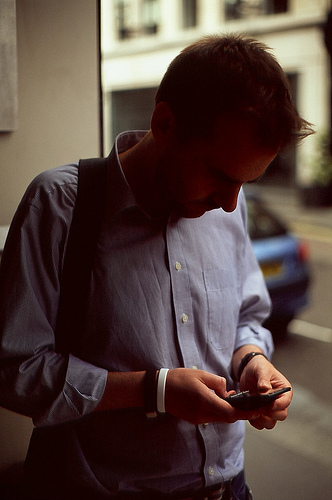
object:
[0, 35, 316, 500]
man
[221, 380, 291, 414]
phone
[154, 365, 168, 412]
bracelet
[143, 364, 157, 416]
bracelet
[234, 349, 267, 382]
watch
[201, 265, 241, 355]
pocket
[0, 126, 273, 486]
shirt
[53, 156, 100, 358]
strap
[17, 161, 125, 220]
shoulder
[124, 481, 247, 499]
belt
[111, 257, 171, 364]
wrinkles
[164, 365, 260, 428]
hands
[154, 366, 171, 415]
wrist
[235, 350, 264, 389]
wrist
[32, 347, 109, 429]
rolled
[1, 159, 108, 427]
sleeve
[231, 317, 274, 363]
rolled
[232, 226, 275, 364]
sleeve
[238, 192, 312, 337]
car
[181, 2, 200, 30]
window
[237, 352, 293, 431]
hand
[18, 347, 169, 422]
arm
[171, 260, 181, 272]
button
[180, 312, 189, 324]
button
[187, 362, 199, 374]
button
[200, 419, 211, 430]
button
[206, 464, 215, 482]
button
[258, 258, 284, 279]
plate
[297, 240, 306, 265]
red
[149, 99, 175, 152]
ear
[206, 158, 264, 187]
looking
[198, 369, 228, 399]
thumb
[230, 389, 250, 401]
button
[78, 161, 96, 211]
black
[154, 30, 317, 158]
hair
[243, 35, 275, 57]
up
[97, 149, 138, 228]
collar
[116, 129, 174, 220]
neck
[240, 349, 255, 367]
buckle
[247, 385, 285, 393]
screen